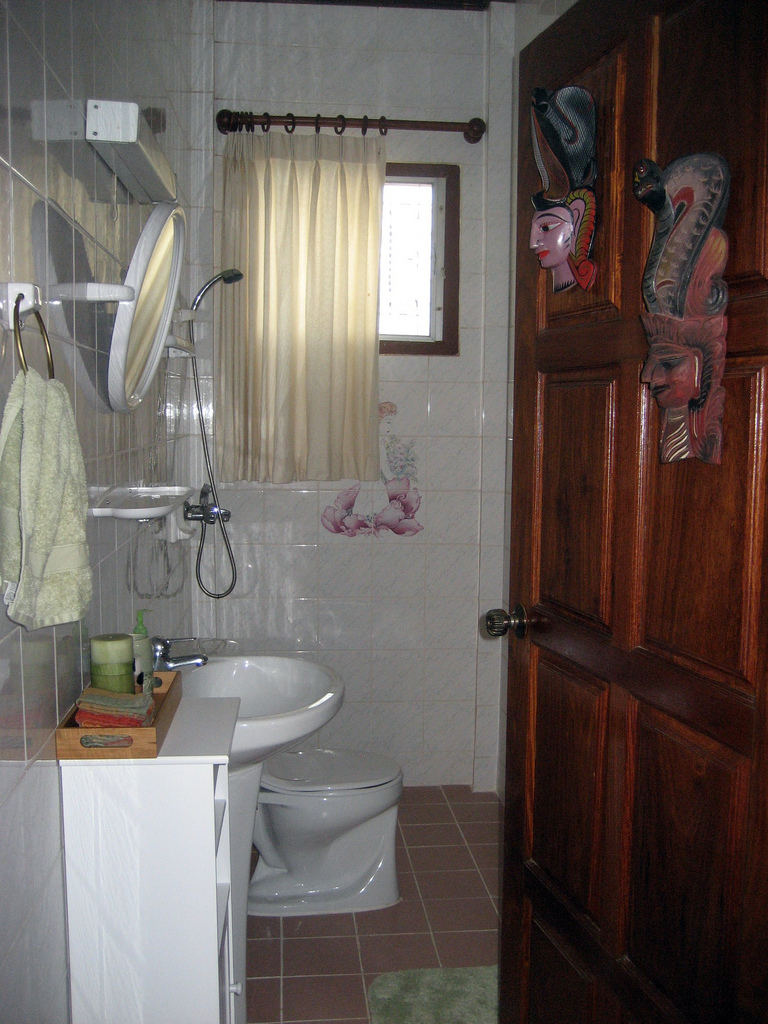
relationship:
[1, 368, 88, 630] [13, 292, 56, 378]
towel hanging on towel ring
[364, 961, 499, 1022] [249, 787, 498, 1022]
bath mat on floor